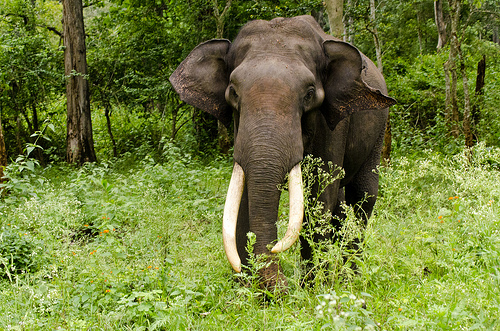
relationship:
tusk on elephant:
[270, 160, 306, 253] [167, 13, 398, 302]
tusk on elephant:
[221, 160, 247, 275] [167, 13, 398, 302]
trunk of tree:
[60, 1, 98, 166] [3, 1, 135, 166]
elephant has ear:
[167, 13, 398, 302] [322, 40, 398, 134]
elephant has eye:
[167, 13, 398, 302] [302, 84, 317, 107]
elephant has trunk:
[167, 13, 398, 302] [246, 168, 287, 302]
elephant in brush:
[167, 13, 398, 302] [1, 149, 499, 329]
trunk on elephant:
[246, 168, 287, 302] [167, 13, 398, 302]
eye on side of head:
[302, 84, 317, 107] [269, 62, 326, 169]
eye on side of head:
[225, 84, 242, 108] [225, 60, 268, 174]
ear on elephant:
[322, 40, 398, 134] [167, 13, 398, 302]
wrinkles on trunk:
[249, 123, 282, 252] [246, 168, 287, 302]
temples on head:
[293, 43, 324, 105] [169, 12, 398, 304]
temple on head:
[223, 46, 249, 117] [169, 12, 398, 304]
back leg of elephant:
[345, 126, 386, 276] [167, 13, 398, 302]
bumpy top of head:
[231, 14, 325, 42] [169, 12, 398, 304]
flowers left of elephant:
[5, 193, 463, 318] [167, 13, 398, 302]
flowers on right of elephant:
[5, 193, 463, 318] [167, 13, 398, 302]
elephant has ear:
[167, 13, 398, 302] [165, 39, 232, 132]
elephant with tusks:
[167, 13, 398, 302] [222, 158, 305, 271]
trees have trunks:
[321, 1, 499, 169] [326, 0, 487, 161]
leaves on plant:
[2, 115, 59, 209] [0, 118, 59, 279]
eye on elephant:
[225, 84, 242, 108] [167, 13, 398, 302]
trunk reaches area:
[246, 168, 287, 302] [0, 0, 499, 168]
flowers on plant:
[5, 193, 463, 318] [62, 211, 161, 298]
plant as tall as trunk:
[302, 153, 378, 297] [246, 168, 287, 302]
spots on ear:
[169, 66, 219, 117] [165, 39, 232, 132]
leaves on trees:
[1, 1, 499, 169] [0, 0, 499, 168]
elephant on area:
[167, 13, 398, 302] [0, 0, 499, 168]